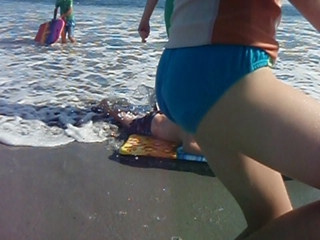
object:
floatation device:
[116, 134, 205, 164]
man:
[51, 0, 77, 43]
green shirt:
[54, 0, 74, 19]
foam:
[0, 27, 320, 147]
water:
[0, 0, 320, 149]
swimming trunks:
[62, 19, 77, 38]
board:
[33, 17, 65, 46]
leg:
[199, 84, 319, 240]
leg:
[193, 134, 293, 239]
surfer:
[136, 0, 320, 240]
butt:
[138, 105, 167, 135]